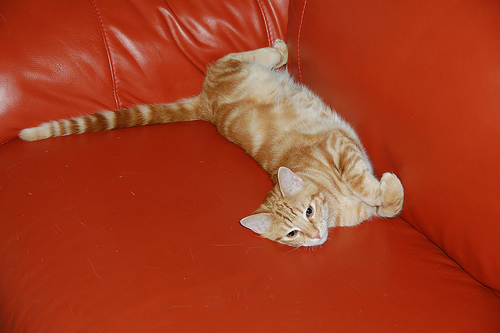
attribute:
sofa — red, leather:
[3, 2, 484, 331]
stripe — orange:
[43, 121, 59, 141]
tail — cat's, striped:
[15, 94, 210, 142]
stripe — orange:
[51, 113, 69, 139]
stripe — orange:
[68, 116, 81, 137]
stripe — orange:
[80, 105, 96, 136]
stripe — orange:
[90, 109, 107, 132]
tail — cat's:
[17, 82, 202, 143]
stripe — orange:
[102, 107, 125, 131]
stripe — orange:
[116, 103, 132, 127]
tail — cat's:
[18, 89, 201, 146]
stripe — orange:
[140, 104, 162, 125]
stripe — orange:
[158, 100, 172, 124]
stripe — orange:
[170, 95, 190, 125]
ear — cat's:
[237, 208, 278, 237]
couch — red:
[9, 63, 497, 324]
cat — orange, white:
[5, 3, 495, 324]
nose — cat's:
[305, 221, 322, 240]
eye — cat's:
[304, 201, 321, 220]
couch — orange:
[5, 11, 497, 309]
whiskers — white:
[281, 235, 308, 260]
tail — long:
[12, 73, 221, 165]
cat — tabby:
[185, 40, 425, 292]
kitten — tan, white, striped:
[21, 34, 417, 263]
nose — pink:
[306, 228, 324, 246]